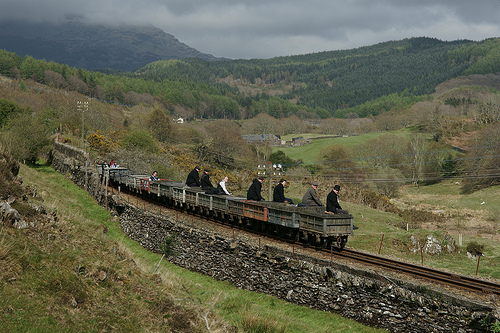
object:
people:
[147, 166, 345, 212]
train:
[100, 153, 354, 248]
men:
[324, 184, 353, 218]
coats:
[325, 190, 344, 211]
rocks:
[0, 193, 33, 231]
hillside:
[3, 145, 167, 332]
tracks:
[110, 183, 496, 297]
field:
[0, 127, 498, 329]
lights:
[73, 93, 94, 151]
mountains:
[135, 31, 493, 103]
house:
[175, 115, 189, 127]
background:
[0, 0, 499, 149]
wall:
[121, 207, 491, 330]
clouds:
[241, 0, 438, 37]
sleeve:
[219, 180, 229, 195]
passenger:
[214, 171, 231, 197]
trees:
[220, 95, 241, 121]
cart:
[241, 199, 270, 221]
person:
[245, 173, 270, 201]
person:
[271, 176, 291, 203]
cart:
[267, 198, 299, 231]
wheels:
[312, 232, 323, 251]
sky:
[2, 0, 498, 58]